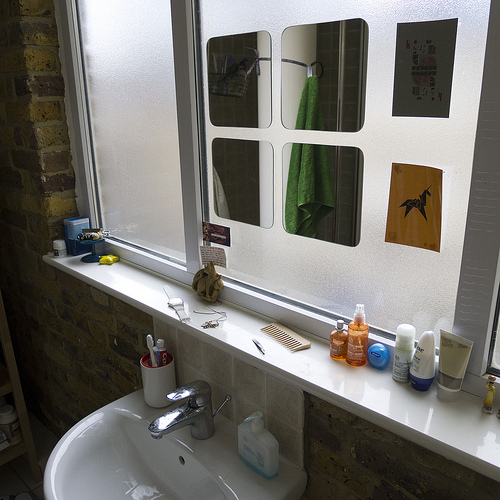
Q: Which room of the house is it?
A: It is a bathroom.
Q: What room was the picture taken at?
A: It was taken at the bathroom.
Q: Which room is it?
A: It is a bathroom.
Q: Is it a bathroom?
A: Yes, it is a bathroom.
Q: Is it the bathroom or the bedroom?
A: It is the bathroom.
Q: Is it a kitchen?
A: No, it is a bathroom.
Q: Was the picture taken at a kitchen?
A: No, the picture was taken in a bathroom.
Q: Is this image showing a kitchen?
A: No, the picture is showing a bathroom.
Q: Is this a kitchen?
A: No, it is a bathroom.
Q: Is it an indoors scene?
A: Yes, it is indoors.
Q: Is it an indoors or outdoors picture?
A: It is indoors.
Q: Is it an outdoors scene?
A: No, it is indoors.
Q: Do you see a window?
A: Yes, there is a window.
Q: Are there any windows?
A: Yes, there is a window.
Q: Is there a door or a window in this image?
A: Yes, there is a window.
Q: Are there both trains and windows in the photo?
A: No, there is a window but no trains.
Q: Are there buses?
A: No, there are no buses.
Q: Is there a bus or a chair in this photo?
A: No, there are no buses or chairs.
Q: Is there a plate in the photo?
A: No, there are no plates.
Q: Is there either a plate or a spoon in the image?
A: No, there are no plates or spoons.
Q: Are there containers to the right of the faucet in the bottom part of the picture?
A: Yes, there is a container to the right of the tap.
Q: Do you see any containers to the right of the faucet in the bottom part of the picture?
A: Yes, there is a container to the right of the tap.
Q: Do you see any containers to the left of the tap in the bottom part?
A: No, the container is to the right of the faucet.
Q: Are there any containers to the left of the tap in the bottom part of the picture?
A: No, the container is to the right of the faucet.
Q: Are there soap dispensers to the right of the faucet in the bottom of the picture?
A: No, there is a container to the right of the tap.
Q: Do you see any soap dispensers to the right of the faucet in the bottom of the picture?
A: No, there is a container to the right of the tap.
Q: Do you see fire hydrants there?
A: No, there are no fire hydrants.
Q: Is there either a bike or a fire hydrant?
A: No, there are no fire hydrants or bikes.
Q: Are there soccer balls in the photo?
A: No, there are no soccer balls.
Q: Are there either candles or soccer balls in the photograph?
A: No, there are no soccer balls or candles.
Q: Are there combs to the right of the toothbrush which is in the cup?
A: Yes, there is a comb to the right of the toothbrush.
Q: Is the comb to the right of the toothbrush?
A: Yes, the comb is to the right of the toothbrush.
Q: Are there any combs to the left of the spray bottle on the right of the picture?
A: Yes, there is a comb to the left of the spray bottle.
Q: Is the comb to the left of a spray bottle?
A: Yes, the comb is to the left of a spray bottle.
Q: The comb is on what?
A: The comb is on the counter.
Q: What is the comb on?
A: The comb is on the counter.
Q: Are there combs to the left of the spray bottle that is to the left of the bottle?
A: Yes, there is a comb to the left of the spray bottle.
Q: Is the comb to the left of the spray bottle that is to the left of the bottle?
A: Yes, the comb is to the left of the spray bottle.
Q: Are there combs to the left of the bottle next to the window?
A: Yes, there is a comb to the left of the bottle.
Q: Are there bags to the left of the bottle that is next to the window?
A: No, there is a comb to the left of the bottle.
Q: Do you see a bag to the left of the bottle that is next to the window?
A: No, there is a comb to the left of the bottle.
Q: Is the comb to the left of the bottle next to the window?
A: Yes, the comb is to the left of the bottle.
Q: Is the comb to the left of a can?
A: No, the comb is to the left of the bottle.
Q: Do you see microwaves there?
A: No, there are no microwaves.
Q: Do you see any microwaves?
A: No, there are no microwaves.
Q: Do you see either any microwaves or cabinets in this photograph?
A: No, there are no microwaves or cabinets.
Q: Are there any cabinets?
A: No, there are no cabinets.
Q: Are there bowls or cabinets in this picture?
A: No, there are no cabinets or bowls.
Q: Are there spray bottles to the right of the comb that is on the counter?
A: Yes, there is a spray bottle to the right of the comb.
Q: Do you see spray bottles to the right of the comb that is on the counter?
A: Yes, there is a spray bottle to the right of the comb.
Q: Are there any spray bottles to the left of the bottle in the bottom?
A: Yes, there is a spray bottle to the left of the bottle.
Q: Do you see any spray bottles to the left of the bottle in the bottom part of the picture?
A: Yes, there is a spray bottle to the left of the bottle.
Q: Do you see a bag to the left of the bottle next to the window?
A: No, there is a spray bottle to the left of the bottle.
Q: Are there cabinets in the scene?
A: No, there are no cabinets.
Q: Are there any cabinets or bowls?
A: No, there are no cabinets or bowls.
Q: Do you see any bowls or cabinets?
A: No, there are no cabinets or bowls.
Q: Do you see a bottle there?
A: Yes, there is a bottle.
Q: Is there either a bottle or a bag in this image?
A: Yes, there is a bottle.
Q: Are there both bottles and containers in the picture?
A: Yes, there are both a bottle and a container.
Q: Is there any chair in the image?
A: No, there are no chairs.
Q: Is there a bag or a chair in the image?
A: No, there are no chairs or bags.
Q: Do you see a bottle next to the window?
A: Yes, there is a bottle next to the window.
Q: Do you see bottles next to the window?
A: Yes, there is a bottle next to the window.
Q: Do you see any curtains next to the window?
A: No, there is a bottle next to the window.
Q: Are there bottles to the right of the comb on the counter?
A: Yes, there is a bottle to the right of the comb.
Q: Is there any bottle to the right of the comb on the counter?
A: Yes, there is a bottle to the right of the comb.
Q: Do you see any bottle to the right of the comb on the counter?
A: Yes, there is a bottle to the right of the comb.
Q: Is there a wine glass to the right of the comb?
A: No, there is a bottle to the right of the comb.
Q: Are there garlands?
A: No, there are no garlands.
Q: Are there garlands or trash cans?
A: No, there are no garlands or trash cans.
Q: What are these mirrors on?
A: The mirrors are on the wall.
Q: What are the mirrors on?
A: The mirrors are on the wall.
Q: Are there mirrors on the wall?
A: Yes, there are mirrors on the wall.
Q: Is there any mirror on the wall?
A: Yes, there are mirrors on the wall.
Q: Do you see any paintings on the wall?
A: No, there are mirrors on the wall.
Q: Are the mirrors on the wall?
A: Yes, the mirrors are on the wall.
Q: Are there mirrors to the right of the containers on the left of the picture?
A: Yes, there are mirrors to the right of the containers.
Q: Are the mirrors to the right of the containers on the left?
A: Yes, the mirrors are to the right of the containers.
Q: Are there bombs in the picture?
A: No, there are no bombs.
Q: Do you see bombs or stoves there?
A: No, there are no bombs or stoves.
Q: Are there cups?
A: Yes, there is a cup.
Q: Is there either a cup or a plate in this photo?
A: Yes, there is a cup.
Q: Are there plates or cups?
A: Yes, there is a cup.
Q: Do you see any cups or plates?
A: Yes, there is a cup.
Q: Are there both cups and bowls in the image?
A: No, there is a cup but no bowls.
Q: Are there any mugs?
A: No, there are no mugs.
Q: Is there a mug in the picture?
A: No, there are no mugs.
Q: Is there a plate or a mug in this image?
A: No, there are no mugs or plates.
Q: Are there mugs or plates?
A: No, there are no mugs or plates.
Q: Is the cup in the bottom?
A: Yes, the cup is in the bottom of the image.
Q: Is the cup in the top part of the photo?
A: No, the cup is in the bottom of the image.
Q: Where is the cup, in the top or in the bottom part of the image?
A: The cup is in the bottom of the image.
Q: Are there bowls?
A: No, there are no bowls.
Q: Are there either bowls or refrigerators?
A: No, there are no bowls or refrigerators.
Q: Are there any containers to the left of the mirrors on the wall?
A: Yes, there are containers to the left of the mirrors.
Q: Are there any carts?
A: No, there are no carts.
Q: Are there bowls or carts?
A: No, there are no carts or bowls.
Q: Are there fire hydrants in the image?
A: No, there are no fire hydrants.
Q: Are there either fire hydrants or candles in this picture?
A: No, there are no fire hydrants or candles.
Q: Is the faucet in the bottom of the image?
A: Yes, the faucet is in the bottom of the image.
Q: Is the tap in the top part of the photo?
A: No, the tap is in the bottom of the image.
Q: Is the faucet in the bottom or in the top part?
A: The faucet is in the bottom of the image.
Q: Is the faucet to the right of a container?
A: No, the faucet is to the left of a container.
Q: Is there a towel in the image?
A: Yes, there is a towel.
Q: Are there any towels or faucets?
A: Yes, there is a towel.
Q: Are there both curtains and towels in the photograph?
A: No, there is a towel but no curtains.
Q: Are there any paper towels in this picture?
A: No, there are no paper towels.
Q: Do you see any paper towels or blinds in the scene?
A: No, there are no paper towels or blinds.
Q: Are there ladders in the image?
A: No, there are no ladders.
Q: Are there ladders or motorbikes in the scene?
A: No, there are no ladders or motorbikes.